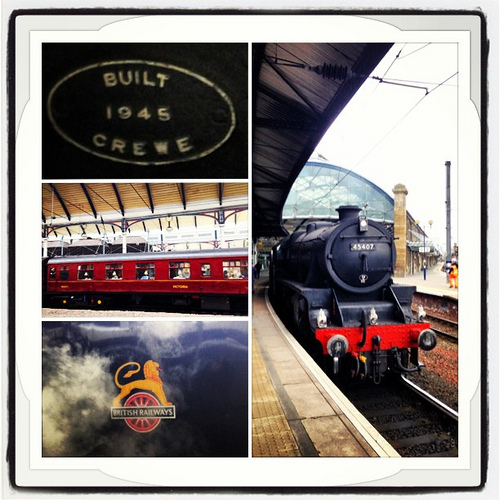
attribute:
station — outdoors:
[267, 152, 462, 469]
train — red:
[43, 247, 257, 309]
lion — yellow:
[99, 353, 183, 433]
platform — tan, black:
[254, 266, 395, 458]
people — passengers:
[141, 269, 191, 280]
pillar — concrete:
[389, 184, 416, 278]